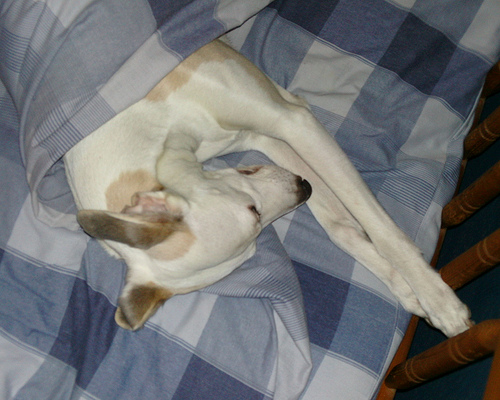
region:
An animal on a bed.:
[59, 34, 471, 346]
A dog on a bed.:
[51, 35, 477, 340]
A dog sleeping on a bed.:
[60, 32, 469, 342]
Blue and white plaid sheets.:
[3, 0, 496, 397]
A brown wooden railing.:
[377, 80, 498, 394]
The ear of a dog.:
[78, 189, 188, 246]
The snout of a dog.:
[230, 161, 314, 216]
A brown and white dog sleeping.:
[62, 38, 473, 345]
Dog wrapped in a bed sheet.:
[0, 4, 478, 339]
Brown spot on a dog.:
[100, 168, 167, 219]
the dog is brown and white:
[43, 29, 483, 361]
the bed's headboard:
[372, 57, 499, 399]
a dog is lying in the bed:
[4, 1, 491, 343]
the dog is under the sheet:
[12, 3, 467, 380]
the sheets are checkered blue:
[2, 2, 499, 399]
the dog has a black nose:
[292, 173, 315, 210]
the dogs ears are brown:
[67, 189, 194, 332]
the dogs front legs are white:
[251, 64, 479, 351]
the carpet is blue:
[390, 87, 498, 396]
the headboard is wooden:
[375, 58, 498, 399]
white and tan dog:
[54, 33, 474, 345]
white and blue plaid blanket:
[0, 4, 487, 399]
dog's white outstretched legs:
[214, 38, 488, 362]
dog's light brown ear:
[71, 175, 205, 255]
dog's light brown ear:
[106, 272, 193, 340]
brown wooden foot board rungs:
[369, 102, 499, 393]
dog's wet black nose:
[291, 167, 313, 212]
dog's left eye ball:
[245, 201, 267, 232]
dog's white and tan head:
[64, 158, 326, 335]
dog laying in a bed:
[16, 22, 496, 369]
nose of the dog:
[285, 154, 327, 216]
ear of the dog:
[58, 184, 185, 291]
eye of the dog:
[232, 190, 279, 234]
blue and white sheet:
[154, 288, 319, 395]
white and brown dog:
[53, 154, 325, 342]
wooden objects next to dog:
[433, 160, 483, 398]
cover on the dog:
[35, 12, 246, 295]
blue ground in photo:
[436, 212, 495, 247]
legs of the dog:
[349, 222, 480, 374]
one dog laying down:
[3, 14, 428, 361]